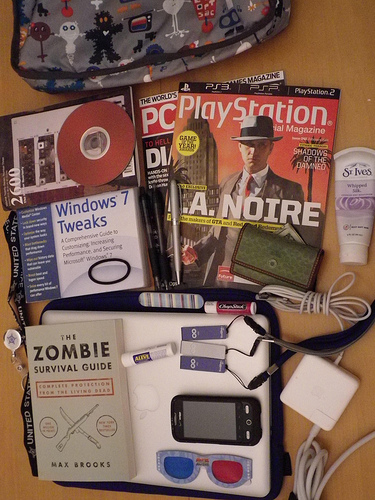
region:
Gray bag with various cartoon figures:
[18, 2, 293, 74]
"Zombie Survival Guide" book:
[31, 322, 123, 487]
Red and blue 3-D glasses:
[157, 451, 253, 484]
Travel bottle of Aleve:
[122, 340, 178, 372]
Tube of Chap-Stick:
[204, 297, 255, 320]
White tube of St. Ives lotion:
[330, 149, 370, 264]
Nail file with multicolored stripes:
[135, 286, 204, 312]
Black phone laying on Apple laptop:
[163, 392, 265, 446]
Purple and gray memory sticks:
[177, 320, 228, 373]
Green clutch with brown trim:
[230, 231, 322, 288]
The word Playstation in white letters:
[180, 89, 330, 130]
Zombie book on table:
[21, 323, 136, 490]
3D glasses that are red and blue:
[145, 448, 260, 489]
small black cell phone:
[163, 388, 259, 445]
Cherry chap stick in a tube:
[199, 297, 272, 313]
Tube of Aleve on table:
[120, 342, 176, 365]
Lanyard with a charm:
[3, 325, 20, 353]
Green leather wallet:
[230, 222, 316, 293]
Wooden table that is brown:
[310, 10, 372, 80]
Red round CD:
[55, 101, 134, 177]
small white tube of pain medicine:
[117, 340, 178, 367]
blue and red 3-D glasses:
[150, 444, 253, 489]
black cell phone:
[167, 391, 262, 447]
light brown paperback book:
[22, 315, 139, 485]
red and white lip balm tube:
[202, 297, 258, 316]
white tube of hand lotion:
[328, 144, 373, 267]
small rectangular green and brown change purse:
[226, 220, 327, 301]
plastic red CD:
[54, 97, 138, 190]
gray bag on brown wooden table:
[8, 0, 295, 95]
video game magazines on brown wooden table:
[134, 69, 345, 297]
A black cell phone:
[164, 386, 264, 444]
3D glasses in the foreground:
[148, 443, 259, 489]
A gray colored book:
[15, 315, 139, 487]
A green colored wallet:
[222, 214, 323, 295]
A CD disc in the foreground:
[50, 98, 140, 188]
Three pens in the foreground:
[131, 177, 197, 292]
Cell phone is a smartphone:
[161, 385, 264, 450]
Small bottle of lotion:
[323, 141, 374, 266]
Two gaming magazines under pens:
[132, 67, 340, 308]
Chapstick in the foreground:
[200, 295, 260, 318]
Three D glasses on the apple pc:
[149, 449, 257, 491]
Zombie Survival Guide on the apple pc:
[21, 323, 139, 484]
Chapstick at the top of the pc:
[202, 300, 261, 314]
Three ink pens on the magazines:
[137, 183, 193, 290]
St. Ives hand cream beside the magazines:
[331, 148, 373, 266]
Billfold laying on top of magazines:
[233, 224, 315, 289]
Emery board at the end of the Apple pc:
[134, 290, 203, 310]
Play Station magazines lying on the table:
[139, 71, 342, 290]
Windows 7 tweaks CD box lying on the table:
[17, 186, 146, 290]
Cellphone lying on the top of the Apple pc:
[165, 392, 263, 444]